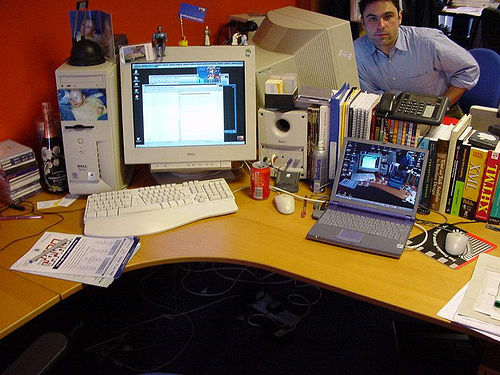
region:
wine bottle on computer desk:
[39, 99, 68, 196]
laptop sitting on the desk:
[303, 133, 421, 260]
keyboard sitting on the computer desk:
[79, 178, 238, 241]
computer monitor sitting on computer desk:
[121, 45, 258, 178]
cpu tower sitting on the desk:
[57, 64, 124, 193]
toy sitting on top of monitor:
[152, 23, 169, 59]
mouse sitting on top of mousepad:
[443, 227, 467, 259]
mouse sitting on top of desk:
[272, 193, 296, 213]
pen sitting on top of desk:
[28, 233, 72, 263]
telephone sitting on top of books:
[373, 85, 444, 124]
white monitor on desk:
[97, 26, 249, 156]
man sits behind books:
[351, 6, 459, 113]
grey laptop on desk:
[313, 148, 414, 285]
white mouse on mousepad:
[437, 217, 488, 276]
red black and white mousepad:
[408, 221, 496, 263]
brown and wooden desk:
[224, 179, 438, 343]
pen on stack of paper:
[26, 232, 90, 263]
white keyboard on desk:
[70, 179, 311, 254]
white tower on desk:
[57, 71, 123, 188]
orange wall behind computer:
[2, 12, 57, 117]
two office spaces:
[3, 0, 498, 373]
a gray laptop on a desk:
[306, 136, 431, 257]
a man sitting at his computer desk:
[353, 1, 480, 111]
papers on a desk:
[10, 229, 140, 287]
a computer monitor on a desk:
[117, 45, 259, 169]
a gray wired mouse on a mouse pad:
[446, 228, 470, 255]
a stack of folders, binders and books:
[308, 80, 499, 227]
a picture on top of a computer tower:
[69, 8, 116, 66]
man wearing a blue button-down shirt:
[353, 25, 478, 105]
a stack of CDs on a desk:
[0, 138, 42, 204]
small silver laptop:
[305, 134, 431, 260]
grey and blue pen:
[24, 233, 71, 264]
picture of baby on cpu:
[57, 86, 108, 121]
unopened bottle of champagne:
[38, 99, 68, 196]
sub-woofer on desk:
[256, 105, 308, 182]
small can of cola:
[247, 158, 269, 200]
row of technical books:
[303, 80, 498, 228]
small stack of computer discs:
[0, 134, 43, 208]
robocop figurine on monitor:
[147, 22, 167, 59]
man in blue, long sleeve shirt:
[352, 0, 482, 113]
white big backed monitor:
[117, 45, 257, 171]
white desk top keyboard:
[82, 175, 236, 233]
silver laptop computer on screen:
[308, 134, 420, 269]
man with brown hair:
[348, 2, 408, 52]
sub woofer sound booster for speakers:
[255, 104, 310, 174]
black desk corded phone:
[375, 83, 448, 130]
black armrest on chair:
[6, 330, 85, 374]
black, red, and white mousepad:
[409, 218, 498, 272]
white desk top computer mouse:
[437, 223, 467, 258]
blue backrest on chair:
[471, 42, 499, 108]